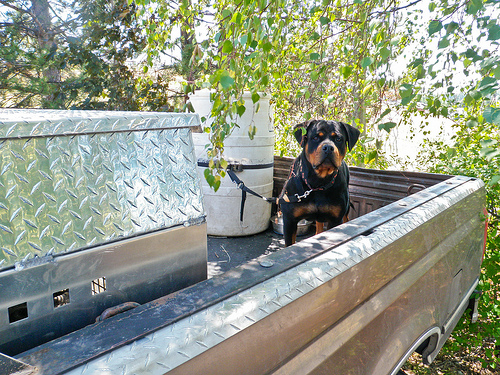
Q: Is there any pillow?
A: No, there are no pillows.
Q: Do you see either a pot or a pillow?
A: No, there are no pillows or pots.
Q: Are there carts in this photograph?
A: No, there are no carts.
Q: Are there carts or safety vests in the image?
A: No, there are no carts or safety vests.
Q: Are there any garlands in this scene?
A: No, there are no garlands.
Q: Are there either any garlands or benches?
A: No, there are no garlands or benches.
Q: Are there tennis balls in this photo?
A: No, there are no tennis balls.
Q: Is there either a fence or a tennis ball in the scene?
A: No, there are no tennis balls or fences.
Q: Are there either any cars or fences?
A: No, there are no cars or fences.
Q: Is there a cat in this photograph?
A: No, there are no cats.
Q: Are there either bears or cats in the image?
A: No, there are no cats or bears.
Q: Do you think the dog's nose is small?
A: Yes, the nose is small.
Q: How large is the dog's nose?
A: The nose is small.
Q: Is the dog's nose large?
A: No, the nose is small.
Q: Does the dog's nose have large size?
A: No, the nose is small.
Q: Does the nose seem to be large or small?
A: The nose is small.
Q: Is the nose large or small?
A: The nose is small.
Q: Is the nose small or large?
A: The nose is small.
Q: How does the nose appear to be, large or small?
A: The nose is small.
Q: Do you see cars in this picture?
A: No, there are no cars.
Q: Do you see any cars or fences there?
A: No, there are no cars or fences.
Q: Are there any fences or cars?
A: No, there are no cars or fences.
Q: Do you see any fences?
A: No, there are no fences.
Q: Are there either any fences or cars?
A: No, there are no fences or cars.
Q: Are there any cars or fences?
A: No, there are no fences or cars.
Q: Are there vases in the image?
A: No, there are no vases.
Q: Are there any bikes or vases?
A: No, there are no vases or bikes.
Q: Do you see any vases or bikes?
A: No, there are no vases or bikes.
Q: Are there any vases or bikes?
A: No, there are no vases or bikes.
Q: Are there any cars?
A: No, there are no cars.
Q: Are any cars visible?
A: No, there are no cars.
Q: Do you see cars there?
A: No, there are no cars.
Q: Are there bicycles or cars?
A: No, there are no cars or bicycles.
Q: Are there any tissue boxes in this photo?
A: No, there are no tissue boxes.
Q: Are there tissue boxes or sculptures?
A: No, there are no tissue boxes or sculptures.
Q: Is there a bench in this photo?
A: No, there are no benches.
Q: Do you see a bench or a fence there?
A: No, there are no benches or fences.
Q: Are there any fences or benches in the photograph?
A: No, there are no benches or fences.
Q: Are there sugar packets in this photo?
A: No, there are no sugar packets.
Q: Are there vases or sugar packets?
A: No, there are no sugar packets or vases.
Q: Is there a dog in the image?
A: Yes, there is a dog.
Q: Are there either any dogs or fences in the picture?
A: Yes, there is a dog.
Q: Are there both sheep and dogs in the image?
A: No, there is a dog but no sheep.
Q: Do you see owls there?
A: No, there are no owls.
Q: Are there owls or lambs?
A: No, there are no owls or lambs.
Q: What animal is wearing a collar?
A: The dog is wearing a collar.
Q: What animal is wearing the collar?
A: The dog is wearing a collar.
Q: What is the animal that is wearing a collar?
A: The animal is a dog.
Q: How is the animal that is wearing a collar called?
A: The animal is a dog.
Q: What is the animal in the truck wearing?
A: The dog is wearing a collar.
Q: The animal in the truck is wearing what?
A: The dog is wearing a collar.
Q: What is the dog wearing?
A: The dog is wearing a collar.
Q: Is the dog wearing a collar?
A: Yes, the dog is wearing a collar.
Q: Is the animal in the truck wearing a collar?
A: Yes, the dog is wearing a collar.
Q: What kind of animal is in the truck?
A: The animal is a dog.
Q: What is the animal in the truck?
A: The animal is a dog.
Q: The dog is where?
A: The dog is in the truck.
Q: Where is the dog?
A: The dog is in the truck.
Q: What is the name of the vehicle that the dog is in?
A: The vehicle is a truck.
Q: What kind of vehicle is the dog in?
A: The dog is in the truck.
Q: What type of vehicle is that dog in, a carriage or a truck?
A: The dog is in a truck.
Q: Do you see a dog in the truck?
A: Yes, there is a dog in the truck.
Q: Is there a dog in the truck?
A: Yes, there is a dog in the truck.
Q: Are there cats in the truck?
A: No, there is a dog in the truck.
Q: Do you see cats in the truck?
A: No, there is a dog in the truck.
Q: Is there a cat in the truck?
A: No, there is a dog in the truck.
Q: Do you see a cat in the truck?
A: No, there is a dog in the truck.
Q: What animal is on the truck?
A: The dog is on the truck.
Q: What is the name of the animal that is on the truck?
A: The animal is a dog.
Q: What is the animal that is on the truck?
A: The animal is a dog.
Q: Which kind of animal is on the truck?
A: The animal is a dog.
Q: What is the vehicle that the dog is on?
A: The vehicle is a truck.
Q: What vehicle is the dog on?
A: The dog is on the truck.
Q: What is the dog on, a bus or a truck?
A: The dog is on a truck.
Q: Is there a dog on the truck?
A: Yes, there is a dog on the truck.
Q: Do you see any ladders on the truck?
A: No, there is a dog on the truck.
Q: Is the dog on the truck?
A: Yes, the dog is on the truck.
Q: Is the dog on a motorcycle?
A: No, the dog is on the truck.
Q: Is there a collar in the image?
A: Yes, there is a collar.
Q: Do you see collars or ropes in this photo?
A: Yes, there is a collar.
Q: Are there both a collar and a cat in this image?
A: No, there is a collar but no cats.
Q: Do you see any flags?
A: No, there are no flags.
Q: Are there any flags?
A: No, there are no flags.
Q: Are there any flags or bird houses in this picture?
A: No, there are no flags or bird houses.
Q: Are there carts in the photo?
A: No, there are no carts.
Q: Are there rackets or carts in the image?
A: No, there are no carts or rackets.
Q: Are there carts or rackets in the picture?
A: No, there are no carts or rackets.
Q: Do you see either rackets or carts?
A: No, there are no carts or rackets.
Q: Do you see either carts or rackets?
A: No, there are no carts or rackets.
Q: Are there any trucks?
A: Yes, there is a truck.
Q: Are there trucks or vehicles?
A: Yes, there is a truck.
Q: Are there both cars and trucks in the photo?
A: No, there is a truck but no cars.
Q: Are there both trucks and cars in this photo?
A: No, there is a truck but no cars.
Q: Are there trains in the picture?
A: No, there are no trains.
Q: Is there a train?
A: No, there are no trains.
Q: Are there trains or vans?
A: No, there are no trains or vans.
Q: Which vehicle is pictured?
A: The vehicle is a truck.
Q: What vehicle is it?
A: The vehicle is a truck.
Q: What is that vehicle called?
A: This is a truck.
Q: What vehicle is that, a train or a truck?
A: This is a truck.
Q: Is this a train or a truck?
A: This is a truck.